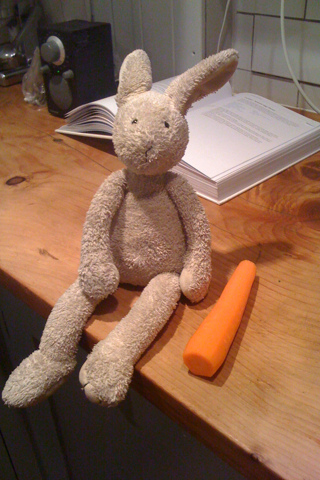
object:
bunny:
[0, 47, 241, 407]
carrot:
[181, 259, 268, 379]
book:
[56, 68, 319, 206]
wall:
[182, 3, 317, 69]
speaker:
[34, 19, 117, 120]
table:
[0, 68, 319, 480]